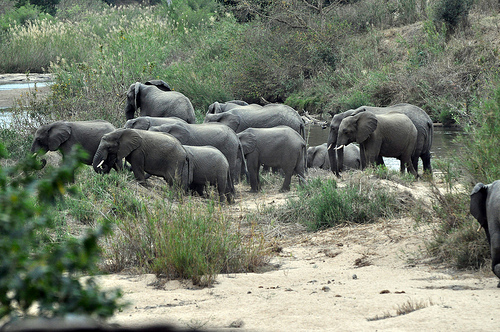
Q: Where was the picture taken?
A: It was taken at the field.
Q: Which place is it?
A: It is a field.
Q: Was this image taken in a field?
A: Yes, it was taken in a field.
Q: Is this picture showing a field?
A: Yes, it is showing a field.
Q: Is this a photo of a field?
A: Yes, it is showing a field.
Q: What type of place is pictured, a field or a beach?
A: It is a field.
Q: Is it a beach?
A: No, it is a field.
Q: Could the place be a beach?
A: No, it is a field.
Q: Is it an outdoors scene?
A: Yes, it is outdoors.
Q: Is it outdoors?
A: Yes, it is outdoors.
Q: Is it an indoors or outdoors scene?
A: It is outdoors.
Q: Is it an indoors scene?
A: No, it is outdoors.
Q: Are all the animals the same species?
A: Yes, all the animals are elephants.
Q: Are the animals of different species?
A: No, all the animals are elephants.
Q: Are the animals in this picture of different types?
A: No, all the animals are elephants.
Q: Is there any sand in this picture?
A: Yes, there is sand.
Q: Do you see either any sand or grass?
A: Yes, there is sand.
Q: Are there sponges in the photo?
A: No, there are no sponges.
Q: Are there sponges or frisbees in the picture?
A: No, there are no sponges or frisbees.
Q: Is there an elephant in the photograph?
A: Yes, there are elephants.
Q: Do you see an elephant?
A: Yes, there are elephants.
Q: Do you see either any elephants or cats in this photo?
A: Yes, there are elephants.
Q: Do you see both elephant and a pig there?
A: No, there are elephants but no pigs.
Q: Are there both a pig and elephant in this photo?
A: No, there are elephants but no pigs.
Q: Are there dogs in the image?
A: No, there are no dogs.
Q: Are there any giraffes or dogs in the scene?
A: No, there are no dogs or giraffes.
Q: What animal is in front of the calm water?
A: The elephants are in front of the water.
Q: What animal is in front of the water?
A: The elephants are in front of the water.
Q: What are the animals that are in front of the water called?
A: The animals are elephants.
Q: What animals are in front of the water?
A: The animals are elephants.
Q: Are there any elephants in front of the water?
A: Yes, there are elephants in front of the water.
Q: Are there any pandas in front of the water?
A: No, there are elephants in front of the water.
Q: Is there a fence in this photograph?
A: No, there are no fences.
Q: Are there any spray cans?
A: No, there are no spray cans.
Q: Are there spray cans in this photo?
A: No, there are no spray cans.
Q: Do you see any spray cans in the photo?
A: No, there are no spray cans.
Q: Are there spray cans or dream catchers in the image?
A: No, there are no spray cans or dream catchers.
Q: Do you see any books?
A: No, there are no books.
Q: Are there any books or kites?
A: No, there are no books or kites.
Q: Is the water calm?
A: Yes, the water is calm.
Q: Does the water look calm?
A: Yes, the water is calm.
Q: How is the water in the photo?
A: The water is calm.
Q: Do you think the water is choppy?
A: No, the water is calm.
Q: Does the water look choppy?
A: No, the water is calm.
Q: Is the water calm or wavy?
A: The water is calm.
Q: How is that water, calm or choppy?
A: The water is calm.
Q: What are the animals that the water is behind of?
A: The animals are elephants.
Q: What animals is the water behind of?
A: The water is behind the elephants.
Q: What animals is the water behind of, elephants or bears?
A: The water is behind elephants.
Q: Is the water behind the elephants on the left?
A: Yes, the water is behind the elephants.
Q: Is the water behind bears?
A: No, the water is behind the elephants.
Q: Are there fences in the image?
A: No, there are no fences.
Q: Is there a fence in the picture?
A: No, there are no fences.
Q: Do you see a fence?
A: No, there are no fences.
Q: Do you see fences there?
A: No, there are no fences.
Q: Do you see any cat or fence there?
A: No, there are no fences or cats.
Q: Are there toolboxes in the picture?
A: No, there are no toolboxes.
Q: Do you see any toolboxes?
A: No, there are no toolboxes.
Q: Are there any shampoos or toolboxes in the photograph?
A: No, there are no toolboxes or shampoos.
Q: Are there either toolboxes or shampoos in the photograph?
A: No, there are no toolboxes or shampoos.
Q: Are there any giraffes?
A: No, there are no giraffes.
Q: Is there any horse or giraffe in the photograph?
A: No, there are no giraffes or horses.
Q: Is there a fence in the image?
A: No, there are no fences.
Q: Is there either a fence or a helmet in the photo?
A: No, there are no fences or helmets.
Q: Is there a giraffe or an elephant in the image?
A: Yes, there is an elephant.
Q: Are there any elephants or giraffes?
A: Yes, there is an elephant.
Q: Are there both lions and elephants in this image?
A: No, there is an elephant but no lions.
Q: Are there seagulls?
A: No, there are no seagulls.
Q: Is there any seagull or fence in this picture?
A: No, there are no seagulls or fences.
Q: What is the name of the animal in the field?
A: The animal is an elephant.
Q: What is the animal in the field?
A: The animal is an elephant.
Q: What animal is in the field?
A: The animal is an elephant.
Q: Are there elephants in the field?
A: Yes, there is an elephant in the field.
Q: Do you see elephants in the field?
A: Yes, there is an elephant in the field.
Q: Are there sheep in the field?
A: No, there is an elephant in the field.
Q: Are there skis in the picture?
A: No, there are no skis.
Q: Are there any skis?
A: No, there are no skis.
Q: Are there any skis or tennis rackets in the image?
A: No, there are no skis or tennis rackets.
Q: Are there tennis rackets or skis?
A: No, there are no skis or tennis rackets.